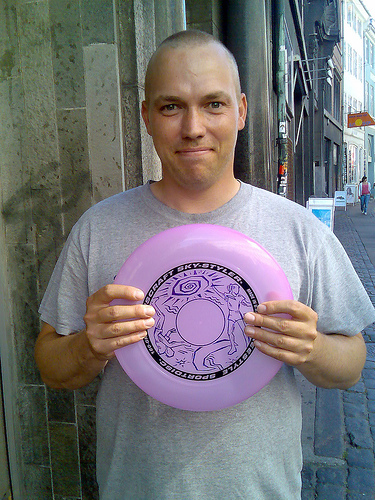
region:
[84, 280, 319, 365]
man's hands holding pink frisbee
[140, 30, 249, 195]
face of man holding frisbee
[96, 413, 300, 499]
bottom part of gray t-shirt man is wearing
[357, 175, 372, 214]
woman in white jacket in background walking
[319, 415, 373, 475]
pavement to right of man holding frisbee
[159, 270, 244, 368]
part of drawing in middle of the pink frisbee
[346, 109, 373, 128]
sign by woman walking in background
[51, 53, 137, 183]
part of wall to left of man holding frisbee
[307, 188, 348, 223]
signs behind the man with the frisbee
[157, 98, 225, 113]
eyes of the man holding the frisbee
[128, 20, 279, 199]
This man is nearly bald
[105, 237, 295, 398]
A logo on the Frisbee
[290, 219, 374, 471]
The side walk is black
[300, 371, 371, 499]
Sidewalk is made of bricks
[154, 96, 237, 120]
He is looking at the camera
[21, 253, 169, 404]
This man is holding the frisbee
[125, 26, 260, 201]
He is white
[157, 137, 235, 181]
There is a smile on his face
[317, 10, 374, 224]
It is sunny outside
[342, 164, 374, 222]
A woman in the background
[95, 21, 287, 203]
happy man's happy face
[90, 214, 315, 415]
man holding purple frisbee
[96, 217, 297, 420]
purple frisbee says sky-styler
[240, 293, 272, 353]
well manicured finger nails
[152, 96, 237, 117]
sparkly, happy green-brown eyes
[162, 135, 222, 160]
smiley pressed lips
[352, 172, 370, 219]
woman in pink walking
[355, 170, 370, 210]
dark haired woman in pink shirt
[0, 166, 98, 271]
faded graffiti on the wall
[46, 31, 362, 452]
man wearing grey shirt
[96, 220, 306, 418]
a pruple frisbee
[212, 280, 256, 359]
a women on the frisbee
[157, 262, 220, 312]
the sun on the frisbee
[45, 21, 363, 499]
the man holding a frisbee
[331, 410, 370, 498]
a black brick sidewalk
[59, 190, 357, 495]
a grey tee shirt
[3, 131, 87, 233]
markings on the wall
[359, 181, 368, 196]
a pink shirt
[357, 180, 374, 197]
the white jacket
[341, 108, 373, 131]
the sign extending from the building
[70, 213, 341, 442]
the frisbee is purple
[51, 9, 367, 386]
the man is smiling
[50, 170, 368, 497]
the man wearing a t shirt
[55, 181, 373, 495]
the t shirt is gray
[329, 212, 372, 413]
the cobble stone street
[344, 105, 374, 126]
the sign on the building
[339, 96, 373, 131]
the sign is hanging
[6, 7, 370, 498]
the buildings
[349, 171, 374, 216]
the person walking on the street